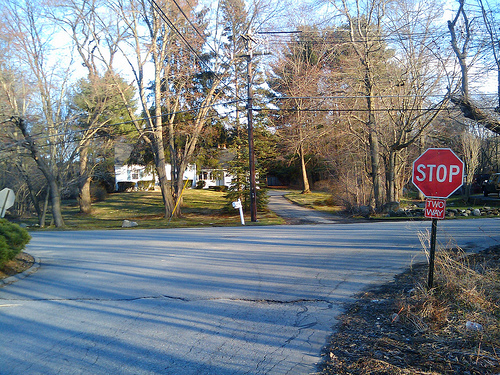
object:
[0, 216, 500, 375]
intersection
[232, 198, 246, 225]
mailbox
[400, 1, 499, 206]
tree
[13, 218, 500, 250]
street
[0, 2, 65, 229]
tree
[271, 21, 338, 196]
tree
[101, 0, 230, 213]
tree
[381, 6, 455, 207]
tree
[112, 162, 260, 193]
house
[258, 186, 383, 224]
driveway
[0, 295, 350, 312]
crack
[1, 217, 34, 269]
bush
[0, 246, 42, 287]
corner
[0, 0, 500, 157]
electric lines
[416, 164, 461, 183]
stop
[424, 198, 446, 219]
sign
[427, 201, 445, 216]
two way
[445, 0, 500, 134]
branch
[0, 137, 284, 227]
wooded area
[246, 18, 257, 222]
pole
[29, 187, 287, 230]
yard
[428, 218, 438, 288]
pole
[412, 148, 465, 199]
sign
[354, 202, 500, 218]
rock wall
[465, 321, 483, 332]
trash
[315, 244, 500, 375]
ground